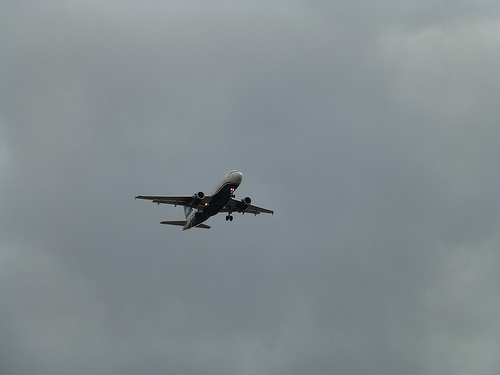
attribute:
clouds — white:
[53, 42, 173, 153]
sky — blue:
[7, 4, 497, 367]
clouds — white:
[167, 25, 357, 140]